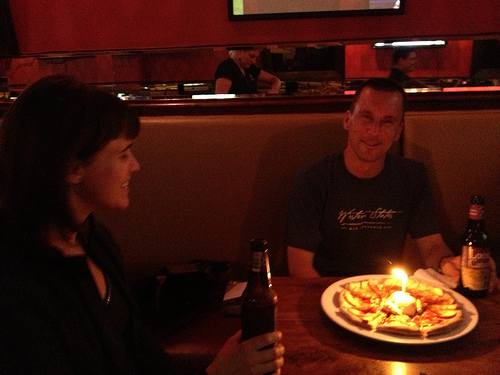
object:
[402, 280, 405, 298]
candle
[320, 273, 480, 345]
plate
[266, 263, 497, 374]
table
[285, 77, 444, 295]
person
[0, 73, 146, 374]
person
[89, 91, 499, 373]
booth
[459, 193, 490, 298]
beer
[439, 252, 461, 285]
hand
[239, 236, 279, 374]
beer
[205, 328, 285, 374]
hand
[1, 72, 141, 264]
hair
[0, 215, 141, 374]
shirt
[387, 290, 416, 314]
ice cream scoop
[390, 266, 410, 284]
flame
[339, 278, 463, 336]
pizza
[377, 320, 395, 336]
slice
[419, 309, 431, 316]
slice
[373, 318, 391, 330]
slice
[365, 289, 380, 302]
slice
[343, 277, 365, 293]
slice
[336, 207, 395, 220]
logo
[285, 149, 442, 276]
tee shirt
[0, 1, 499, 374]
restaurant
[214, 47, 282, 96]
person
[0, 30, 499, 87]
restaurant kitchen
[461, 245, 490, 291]
label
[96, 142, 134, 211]
face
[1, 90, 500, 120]
bar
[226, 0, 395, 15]
mirror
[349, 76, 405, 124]
hair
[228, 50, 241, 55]
hair